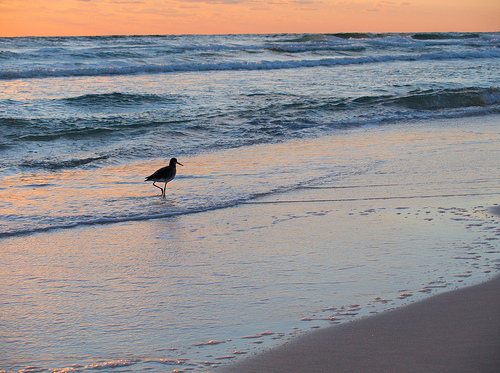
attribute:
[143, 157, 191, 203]
bird — walking, black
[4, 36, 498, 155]
water — wavy, calm, coorles, blue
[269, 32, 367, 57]
waves — heavy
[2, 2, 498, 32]
sky — cream, cloudy, clear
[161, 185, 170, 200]
these — legs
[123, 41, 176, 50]
these — waves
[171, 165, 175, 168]
these — feathers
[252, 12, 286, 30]
ray — reflected